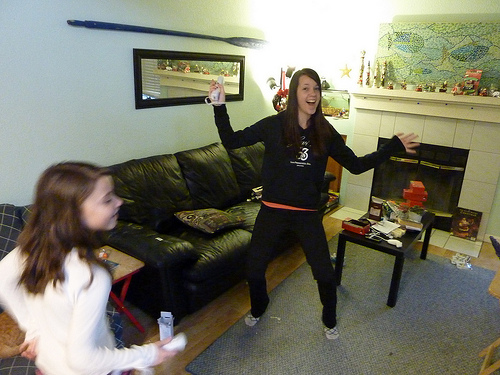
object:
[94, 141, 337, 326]
couch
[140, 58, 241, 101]
mirror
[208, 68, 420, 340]
girl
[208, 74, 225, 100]
remote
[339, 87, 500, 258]
fireplace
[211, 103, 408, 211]
sweatshirt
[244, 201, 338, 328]
pants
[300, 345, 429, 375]
rug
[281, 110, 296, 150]
hair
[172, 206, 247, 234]
cushion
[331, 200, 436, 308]
coffee table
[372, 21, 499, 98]
picture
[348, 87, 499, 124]
mantle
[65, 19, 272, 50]
paddle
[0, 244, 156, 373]
shirt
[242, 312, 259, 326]
sock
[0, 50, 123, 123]
wall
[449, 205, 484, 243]
book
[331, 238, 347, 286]
leg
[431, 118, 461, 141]
tile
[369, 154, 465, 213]
screen